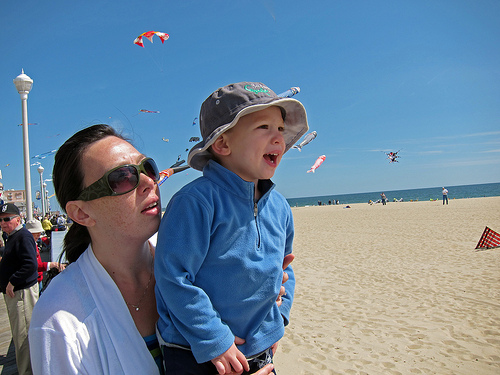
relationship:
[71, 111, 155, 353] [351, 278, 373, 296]
woman at beach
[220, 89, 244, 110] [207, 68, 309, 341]
hat on boy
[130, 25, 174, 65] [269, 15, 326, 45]
kite in sky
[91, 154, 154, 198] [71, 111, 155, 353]
sunglasses on woman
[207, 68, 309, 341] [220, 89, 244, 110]
boy wearing hat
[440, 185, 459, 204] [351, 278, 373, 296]
man on beach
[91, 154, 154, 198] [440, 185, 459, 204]
sunglasses on man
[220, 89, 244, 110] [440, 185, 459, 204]
hat on man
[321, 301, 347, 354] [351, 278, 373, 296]
sand on beach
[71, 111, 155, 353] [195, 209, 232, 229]
woman wearing sweater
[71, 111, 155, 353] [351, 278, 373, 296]
woman on beach